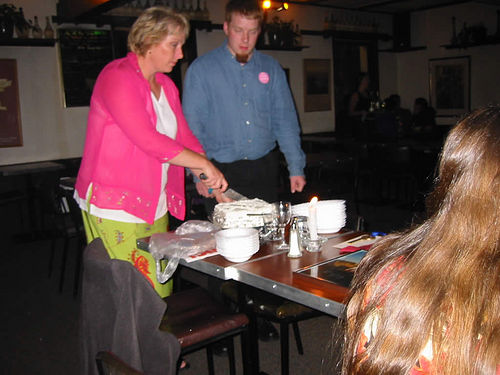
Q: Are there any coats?
A: Yes, there is a coat.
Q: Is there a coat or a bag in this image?
A: Yes, there is a coat.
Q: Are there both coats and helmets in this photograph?
A: No, there is a coat but no helmets.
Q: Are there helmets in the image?
A: No, there are no helmets.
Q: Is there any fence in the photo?
A: No, there are no fences.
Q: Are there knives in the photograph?
A: Yes, there is a knife.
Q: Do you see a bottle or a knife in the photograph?
A: Yes, there is a knife.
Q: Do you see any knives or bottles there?
A: Yes, there is a knife.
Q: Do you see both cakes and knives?
A: Yes, there are both a knife and a cake.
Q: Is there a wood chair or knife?
A: Yes, there is a wood knife.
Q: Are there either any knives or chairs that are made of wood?
A: Yes, the knife is made of wood.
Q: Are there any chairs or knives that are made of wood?
A: Yes, the knife is made of wood.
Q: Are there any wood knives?
A: Yes, there is a wood knife.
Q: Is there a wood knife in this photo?
A: Yes, there is a wood knife.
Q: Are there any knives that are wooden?
A: Yes, there is a knife that is wooden.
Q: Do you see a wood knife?
A: Yes, there is a knife that is made of wood.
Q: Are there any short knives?
A: Yes, there is a short knife.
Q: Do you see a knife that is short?
A: Yes, there is a knife that is short.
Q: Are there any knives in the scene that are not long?
A: Yes, there is a short knife.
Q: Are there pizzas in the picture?
A: No, there are no pizzas.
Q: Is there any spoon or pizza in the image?
A: No, there are no pizzas or spoons.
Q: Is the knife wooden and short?
A: Yes, the knife is wooden and short.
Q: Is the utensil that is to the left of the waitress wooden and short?
A: Yes, the knife is wooden and short.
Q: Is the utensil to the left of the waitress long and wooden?
A: No, the knife is wooden but short.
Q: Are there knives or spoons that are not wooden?
A: No, there is a knife but it is wooden.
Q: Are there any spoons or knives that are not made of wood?
A: No, there is a knife but it is made of wood.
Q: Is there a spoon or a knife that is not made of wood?
A: No, there is a knife but it is made of wood.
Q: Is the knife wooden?
A: Yes, the knife is wooden.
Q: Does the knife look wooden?
A: Yes, the knife is wooden.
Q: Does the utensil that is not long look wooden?
A: Yes, the knife is wooden.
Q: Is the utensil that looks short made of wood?
A: Yes, the knife is made of wood.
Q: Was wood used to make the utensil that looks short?
A: Yes, the knife is made of wood.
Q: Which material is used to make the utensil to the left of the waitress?
A: The knife is made of wood.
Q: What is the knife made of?
A: The knife is made of wood.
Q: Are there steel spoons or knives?
A: No, there is a knife but it is wooden.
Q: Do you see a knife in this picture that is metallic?
A: No, there is a knife but it is wooden.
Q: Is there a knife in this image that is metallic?
A: No, there is a knife but it is wooden.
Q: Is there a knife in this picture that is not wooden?
A: No, there is a knife but it is wooden.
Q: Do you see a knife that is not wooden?
A: No, there is a knife but it is wooden.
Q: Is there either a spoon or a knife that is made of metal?
A: No, there is a knife but it is made of wood.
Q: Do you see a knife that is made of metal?
A: No, there is a knife but it is made of wood.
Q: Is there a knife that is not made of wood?
A: No, there is a knife but it is made of wood.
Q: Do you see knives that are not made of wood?
A: No, there is a knife but it is made of wood.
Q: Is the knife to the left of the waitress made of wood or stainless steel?
A: The knife is made of wood.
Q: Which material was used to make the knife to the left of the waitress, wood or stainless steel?
A: The knife is made of wood.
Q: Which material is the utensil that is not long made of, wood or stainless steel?
A: The knife is made of wood.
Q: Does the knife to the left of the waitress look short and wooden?
A: Yes, the knife is short and wooden.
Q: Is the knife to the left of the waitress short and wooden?
A: Yes, the knife is short and wooden.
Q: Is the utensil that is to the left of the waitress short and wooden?
A: Yes, the knife is short and wooden.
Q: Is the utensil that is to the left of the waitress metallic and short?
A: No, the knife is short but wooden.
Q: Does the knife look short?
A: Yes, the knife is short.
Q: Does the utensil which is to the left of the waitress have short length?
A: Yes, the knife is short.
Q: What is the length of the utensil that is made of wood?
A: The knife is short.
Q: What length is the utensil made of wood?
A: The knife is short.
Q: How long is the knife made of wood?
A: The knife is short.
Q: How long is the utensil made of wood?
A: The knife is short.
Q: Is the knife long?
A: No, the knife is short.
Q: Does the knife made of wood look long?
A: No, the knife is short.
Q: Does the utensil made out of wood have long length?
A: No, the knife is short.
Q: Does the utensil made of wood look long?
A: No, the knife is short.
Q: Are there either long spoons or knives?
A: No, there is a knife but it is short.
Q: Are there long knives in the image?
A: No, there is a knife but it is short.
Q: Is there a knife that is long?
A: No, there is a knife but it is short.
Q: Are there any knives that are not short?
A: No, there is a knife but it is short.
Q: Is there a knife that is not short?
A: No, there is a knife but it is short.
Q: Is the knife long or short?
A: The knife is short.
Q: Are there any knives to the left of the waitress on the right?
A: Yes, there is a knife to the left of the waitress.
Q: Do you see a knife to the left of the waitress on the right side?
A: Yes, there is a knife to the left of the waitress.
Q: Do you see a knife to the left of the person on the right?
A: Yes, there is a knife to the left of the waitress.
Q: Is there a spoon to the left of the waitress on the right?
A: No, there is a knife to the left of the waitress.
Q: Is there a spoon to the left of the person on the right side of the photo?
A: No, there is a knife to the left of the waitress.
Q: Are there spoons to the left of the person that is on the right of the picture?
A: No, there is a knife to the left of the waitress.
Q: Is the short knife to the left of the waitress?
A: Yes, the knife is to the left of the waitress.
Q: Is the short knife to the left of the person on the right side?
A: Yes, the knife is to the left of the waitress.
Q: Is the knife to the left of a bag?
A: No, the knife is to the left of the waitress.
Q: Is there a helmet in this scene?
A: No, there are no helmets.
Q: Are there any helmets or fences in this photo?
A: No, there are no helmets or fences.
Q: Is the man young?
A: Yes, the man is young.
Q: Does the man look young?
A: Yes, the man is young.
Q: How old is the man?
A: The man is young.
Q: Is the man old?
A: No, the man is young.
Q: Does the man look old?
A: No, the man is young.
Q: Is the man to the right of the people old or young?
A: The man is young.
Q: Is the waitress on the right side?
A: Yes, the waitress is on the right of the image.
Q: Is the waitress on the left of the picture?
A: No, the waitress is on the right of the image.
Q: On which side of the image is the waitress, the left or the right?
A: The waitress is on the right of the image.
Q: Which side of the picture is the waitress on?
A: The waitress is on the right of the image.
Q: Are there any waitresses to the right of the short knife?
A: Yes, there is a waitress to the right of the knife.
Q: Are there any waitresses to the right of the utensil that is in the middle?
A: Yes, there is a waitress to the right of the knife.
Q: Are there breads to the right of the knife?
A: No, there is a waitress to the right of the knife.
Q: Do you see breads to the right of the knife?
A: No, there is a waitress to the right of the knife.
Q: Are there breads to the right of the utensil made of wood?
A: No, there is a waitress to the right of the knife.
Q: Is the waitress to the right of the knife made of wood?
A: Yes, the waitress is to the right of the knife.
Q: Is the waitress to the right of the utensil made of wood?
A: Yes, the waitress is to the right of the knife.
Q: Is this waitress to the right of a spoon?
A: No, the waitress is to the right of the knife.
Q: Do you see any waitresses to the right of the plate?
A: Yes, there is a waitress to the right of the plate.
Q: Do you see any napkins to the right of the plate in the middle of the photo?
A: No, there is a waitress to the right of the plate.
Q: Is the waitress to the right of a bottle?
A: No, the waitress is to the right of the plate.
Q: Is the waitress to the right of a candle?
A: Yes, the waitress is to the right of a candle.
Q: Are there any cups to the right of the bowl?
A: No, there is a waitress to the right of the bowl.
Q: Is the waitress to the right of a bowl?
A: Yes, the waitress is to the right of a bowl.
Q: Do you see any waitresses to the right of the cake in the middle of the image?
A: Yes, there is a waitress to the right of the cake.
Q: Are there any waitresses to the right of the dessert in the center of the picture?
A: Yes, there is a waitress to the right of the cake.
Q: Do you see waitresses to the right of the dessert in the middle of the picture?
A: Yes, there is a waitress to the right of the cake.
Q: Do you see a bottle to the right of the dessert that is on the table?
A: No, there is a waitress to the right of the cake.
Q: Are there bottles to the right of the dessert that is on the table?
A: No, there is a waitress to the right of the cake.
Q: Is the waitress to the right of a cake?
A: Yes, the waitress is to the right of a cake.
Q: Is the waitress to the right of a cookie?
A: No, the waitress is to the right of a cake.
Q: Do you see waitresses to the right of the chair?
A: Yes, there is a waitress to the right of the chair.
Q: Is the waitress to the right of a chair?
A: Yes, the waitress is to the right of a chair.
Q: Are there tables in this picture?
A: Yes, there is a table.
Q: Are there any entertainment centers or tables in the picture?
A: Yes, there is a table.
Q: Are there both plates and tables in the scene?
A: Yes, there are both a table and a plate.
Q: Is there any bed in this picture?
A: No, there are no beds.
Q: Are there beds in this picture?
A: No, there are no beds.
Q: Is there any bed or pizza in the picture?
A: No, there are no beds or pizzas.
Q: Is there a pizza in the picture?
A: No, there are no pizzas.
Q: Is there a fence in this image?
A: No, there are no fences.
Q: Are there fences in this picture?
A: No, there are no fences.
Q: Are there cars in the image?
A: No, there are no cars.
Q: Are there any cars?
A: No, there are no cars.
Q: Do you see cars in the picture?
A: No, there are no cars.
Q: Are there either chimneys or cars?
A: No, there are no cars or chimneys.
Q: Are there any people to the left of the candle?
A: Yes, there are people to the left of the candle.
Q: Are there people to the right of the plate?
A: No, the people are to the left of the plate.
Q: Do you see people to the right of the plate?
A: No, the people are to the left of the plate.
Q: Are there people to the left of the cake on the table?
A: Yes, there are people to the left of the cake.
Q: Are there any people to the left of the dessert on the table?
A: Yes, there are people to the left of the cake.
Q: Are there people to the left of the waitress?
A: Yes, there are people to the left of the waitress.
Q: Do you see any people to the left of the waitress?
A: Yes, there are people to the left of the waitress.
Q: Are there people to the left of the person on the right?
A: Yes, there are people to the left of the waitress.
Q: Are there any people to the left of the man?
A: Yes, there are people to the left of the man.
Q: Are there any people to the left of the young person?
A: Yes, there are people to the left of the man.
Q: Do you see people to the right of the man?
A: No, the people are to the left of the man.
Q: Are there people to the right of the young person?
A: No, the people are to the left of the man.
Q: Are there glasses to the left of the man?
A: No, there are people to the left of the man.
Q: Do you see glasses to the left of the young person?
A: No, there are people to the left of the man.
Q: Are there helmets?
A: No, there are no helmets.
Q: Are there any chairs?
A: Yes, there is a chair.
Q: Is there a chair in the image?
A: Yes, there is a chair.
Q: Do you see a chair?
A: Yes, there is a chair.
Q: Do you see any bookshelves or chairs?
A: Yes, there is a chair.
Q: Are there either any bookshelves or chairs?
A: Yes, there is a chair.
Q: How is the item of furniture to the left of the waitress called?
A: The piece of furniture is a chair.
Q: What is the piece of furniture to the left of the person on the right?
A: The piece of furniture is a chair.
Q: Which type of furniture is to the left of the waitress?
A: The piece of furniture is a chair.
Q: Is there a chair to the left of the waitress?
A: Yes, there is a chair to the left of the waitress.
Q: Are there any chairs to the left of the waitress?
A: Yes, there is a chair to the left of the waitress.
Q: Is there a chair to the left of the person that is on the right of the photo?
A: Yes, there is a chair to the left of the waitress.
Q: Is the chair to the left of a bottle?
A: No, the chair is to the left of the waitress.